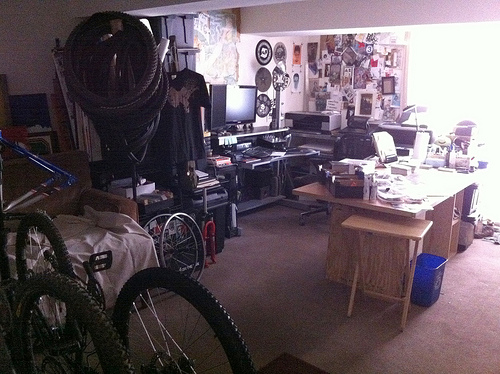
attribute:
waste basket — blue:
[417, 246, 447, 308]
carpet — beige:
[222, 207, 497, 372]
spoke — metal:
[175, 311, 217, 349]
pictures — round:
[254, 35, 295, 129]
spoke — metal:
[129, 285, 191, 372]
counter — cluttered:
[322, 139, 452, 240]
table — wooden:
[329, 205, 436, 331]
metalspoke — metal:
[125, 288, 230, 372]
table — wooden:
[295, 148, 490, 300]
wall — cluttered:
[225, 18, 444, 125]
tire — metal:
[107, 247, 276, 372]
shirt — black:
[158, 64, 235, 169]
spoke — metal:
[26, 225, 37, 274]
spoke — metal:
[146, 290, 166, 362]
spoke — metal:
[134, 299, 156, 355]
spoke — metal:
[141, 283, 183, 352]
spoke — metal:
[178, 296, 189, 350]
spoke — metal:
[185, 308, 199, 343]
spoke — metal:
[197, 329, 215, 365]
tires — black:
[2, 193, 265, 369]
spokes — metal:
[53, 300, 195, 365]